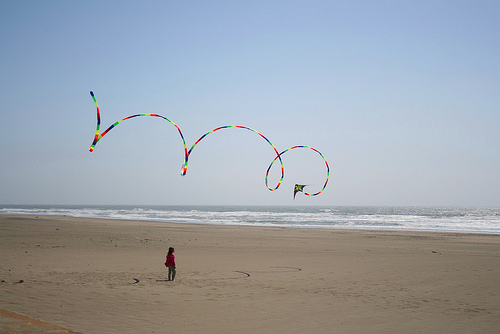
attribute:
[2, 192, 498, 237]
water — white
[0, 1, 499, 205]
sky — clear, blue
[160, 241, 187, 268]
shirt — red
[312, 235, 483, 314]
sand — brown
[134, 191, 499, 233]
waves — white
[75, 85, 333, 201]
kite — black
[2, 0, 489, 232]
sky — clear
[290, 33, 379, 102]
sky — clear, light blue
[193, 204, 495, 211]
waters — calm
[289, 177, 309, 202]
kite — black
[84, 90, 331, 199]
tail — long, rainbow